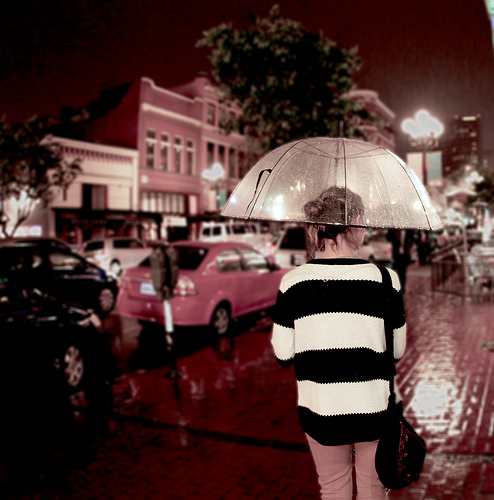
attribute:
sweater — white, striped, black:
[270, 256, 409, 444]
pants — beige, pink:
[307, 428, 395, 499]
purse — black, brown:
[372, 402, 430, 493]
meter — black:
[144, 244, 181, 366]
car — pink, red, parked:
[112, 238, 297, 333]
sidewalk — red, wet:
[2, 258, 492, 499]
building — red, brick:
[84, 77, 207, 213]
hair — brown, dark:
[300, 184, 363, 253]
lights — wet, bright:
[400, 105, 443, 144]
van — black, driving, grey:
[2, 238, 120, 312]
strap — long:
[376, 262, 404, 409]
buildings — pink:
[96, 69, 269, 224]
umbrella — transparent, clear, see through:
[216, 122, 450, 240]